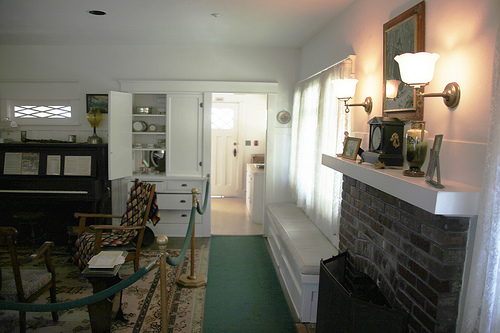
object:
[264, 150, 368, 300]
window bench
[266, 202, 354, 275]
cushion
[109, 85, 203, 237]
cabinet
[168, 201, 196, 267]
rope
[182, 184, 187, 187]
handle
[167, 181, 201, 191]
drawer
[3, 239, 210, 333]
rug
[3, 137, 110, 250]
piano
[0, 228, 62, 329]
stool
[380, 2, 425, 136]
frame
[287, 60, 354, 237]
curtains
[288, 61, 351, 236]
window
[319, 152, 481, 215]
mantle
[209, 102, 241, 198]
door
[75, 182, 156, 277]
chair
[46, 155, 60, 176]
sheet music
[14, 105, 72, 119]
window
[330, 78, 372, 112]
lights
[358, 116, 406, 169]
clock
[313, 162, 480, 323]
yellow ball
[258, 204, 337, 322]
chest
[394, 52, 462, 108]
lamp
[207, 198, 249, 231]
floor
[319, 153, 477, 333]
fireplace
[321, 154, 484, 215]
fireplace mantle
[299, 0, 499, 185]
wall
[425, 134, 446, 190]
picture frame